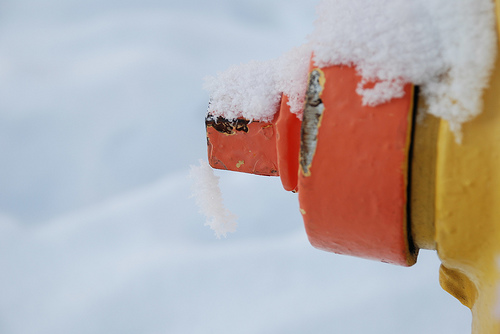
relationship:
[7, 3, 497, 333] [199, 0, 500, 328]
snow piled on top of fire hydrant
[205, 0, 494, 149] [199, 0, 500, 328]
snow behind fire hydrant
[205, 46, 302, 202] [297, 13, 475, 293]
screw attached to fitting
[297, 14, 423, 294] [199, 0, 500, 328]
fitting attached to fire hydrant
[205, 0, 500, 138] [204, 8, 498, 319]
snow on hydrant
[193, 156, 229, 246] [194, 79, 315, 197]
snow hanging from screw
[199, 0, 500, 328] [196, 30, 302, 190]
fire hydrant has cap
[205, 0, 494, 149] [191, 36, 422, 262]
snow covering cap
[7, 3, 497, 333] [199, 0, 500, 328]
snow below fire hydrant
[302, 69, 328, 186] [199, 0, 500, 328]
chipped paint on fire hydrant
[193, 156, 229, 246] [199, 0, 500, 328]
snow hanging from fire hydrant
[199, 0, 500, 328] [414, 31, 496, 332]
fire hydrant has body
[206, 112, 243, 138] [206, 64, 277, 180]
rust on end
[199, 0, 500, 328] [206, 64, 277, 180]
fire hydrant has end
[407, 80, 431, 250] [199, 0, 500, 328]
threads on fire hydrant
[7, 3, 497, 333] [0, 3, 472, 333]
snow covering ground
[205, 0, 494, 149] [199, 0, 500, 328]
snow on fire hydrant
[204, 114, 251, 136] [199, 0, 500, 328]
chipped paint on fire hydrant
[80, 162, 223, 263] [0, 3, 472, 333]
snow on ground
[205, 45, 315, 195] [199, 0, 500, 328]
tip on fire hydrant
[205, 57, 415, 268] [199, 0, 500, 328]
orange on fire hydrant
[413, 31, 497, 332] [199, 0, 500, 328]
yellow on fire hydrant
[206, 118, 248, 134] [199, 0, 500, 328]
hole in fire hydrant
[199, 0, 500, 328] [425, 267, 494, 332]
fire hydrant has bottom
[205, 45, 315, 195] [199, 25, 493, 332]
part on fire hydrant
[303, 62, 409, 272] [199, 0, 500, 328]
part on fire hydrant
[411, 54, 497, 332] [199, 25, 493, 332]
part on fire hydrant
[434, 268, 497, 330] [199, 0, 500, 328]
part on fire hydrant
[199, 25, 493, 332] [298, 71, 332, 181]
fire hydrant has part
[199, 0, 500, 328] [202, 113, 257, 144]
fire hydrant has part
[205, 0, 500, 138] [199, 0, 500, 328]
snow covering fire hydrant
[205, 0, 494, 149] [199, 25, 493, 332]
snow covering fire hydrant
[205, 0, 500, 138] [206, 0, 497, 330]
snow on fire hydrant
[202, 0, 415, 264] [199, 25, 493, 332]
cap on fire hydrant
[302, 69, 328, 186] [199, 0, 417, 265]
chipped paint on cap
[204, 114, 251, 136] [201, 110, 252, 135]
chipped paint under snow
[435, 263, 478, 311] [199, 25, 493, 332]
corner on fire hydrant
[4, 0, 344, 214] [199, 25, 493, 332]
snow patch behind fire hydrant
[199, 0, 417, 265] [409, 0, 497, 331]
cap meets hydrant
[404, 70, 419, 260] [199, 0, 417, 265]
seamline on cap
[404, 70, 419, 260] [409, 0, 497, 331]
seamline on hydrant